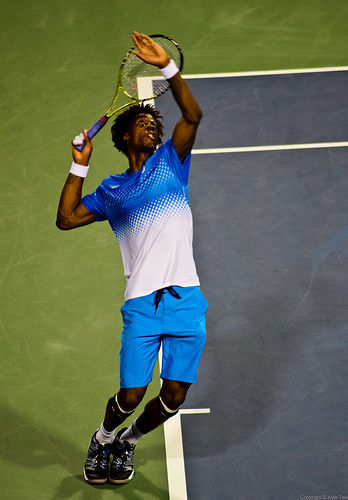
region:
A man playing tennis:
[52, 25, 210, 486]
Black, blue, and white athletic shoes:
[81, 426, 141, 487]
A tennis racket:
[72, 31, 183, 151]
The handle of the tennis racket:
[73, 114, 107, 153]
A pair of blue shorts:
[115, 282, 210, 388]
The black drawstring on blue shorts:
[150, 285, 182, 314]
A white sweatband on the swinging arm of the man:
[66, 160, 91, 178]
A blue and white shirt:
[80, 135, 202, 300]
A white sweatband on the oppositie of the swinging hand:
[153, 59, 183, 80]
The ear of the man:
[120, 129, 129, 141]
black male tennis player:
[46, 18, 227, 358]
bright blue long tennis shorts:
[112, 287, 218, 409]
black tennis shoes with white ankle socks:
[78, 419, 158, 489]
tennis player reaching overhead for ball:
[41, 13, 227, 239]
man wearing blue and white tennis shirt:
[54, 93, 222, 306]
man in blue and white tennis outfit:
[54, 58, 215, 450]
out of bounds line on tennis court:
[148, 330, 199, 496]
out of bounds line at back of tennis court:
[122, 40, 345, 141]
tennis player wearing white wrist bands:
[58, 22, 219, 239]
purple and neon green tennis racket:
[65, 24, 189, 160]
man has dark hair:
[106, 106, 154, 161]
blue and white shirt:
[73, 134, 186, 280]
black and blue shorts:
[117, 263, 222, 388]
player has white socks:
[94, 413, 148, 449]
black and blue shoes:
[88, 440, 144, 489]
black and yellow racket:
[112, 29, 186, 112]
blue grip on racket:
[74, 110, 108, 149]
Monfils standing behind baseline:
[60, 20, 198, 487]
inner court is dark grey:
[174, 89, 341, 493]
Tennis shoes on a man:
[79, 418, 151, 490]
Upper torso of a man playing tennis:
[53, 24, 218, 255]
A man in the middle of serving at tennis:
[40, 19, 220, 489]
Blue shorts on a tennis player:
[105, 282, 220, 391]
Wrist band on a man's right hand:
[62, 157, 95, 181]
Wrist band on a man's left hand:
[154, 59, 193, 84]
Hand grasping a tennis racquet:
[64, 121, 104, 166]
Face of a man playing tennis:
[101, 100, 170, 181]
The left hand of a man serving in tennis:
[120, 21, 169, 68]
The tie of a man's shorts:
[144, 280, 189, 317]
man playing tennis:
[39, 12, 344, 471]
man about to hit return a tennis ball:
[57, 36, 225, 485]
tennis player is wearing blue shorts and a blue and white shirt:
[82, 137, 212, 394]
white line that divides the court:
[126, 72, 203, 495]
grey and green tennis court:
[4, 24, 343, 496]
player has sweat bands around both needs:
[101, 396, 186, 421]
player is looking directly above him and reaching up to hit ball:
[54, 43, 196, 485]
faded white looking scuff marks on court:
[4, 89, 99, 422]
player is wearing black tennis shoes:
[82, 425, 131, 481]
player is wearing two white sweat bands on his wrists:
[62, 59, 199, 177]